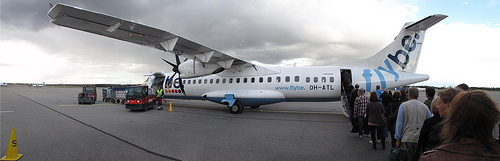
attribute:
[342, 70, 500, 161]
people — in line, waiting, boarding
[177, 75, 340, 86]
windows — black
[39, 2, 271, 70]
wings — long, white, large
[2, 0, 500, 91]
sky — blue, dark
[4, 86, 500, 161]
tarmac — grey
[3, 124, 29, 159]
cone — yellow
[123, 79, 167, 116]
truck — red, servicing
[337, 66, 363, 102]
door — open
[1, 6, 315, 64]
clouds — grey, dark, white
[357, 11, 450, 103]
tail — white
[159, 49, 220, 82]
engine — white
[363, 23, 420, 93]
words — blue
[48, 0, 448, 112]
plane — white, waiting